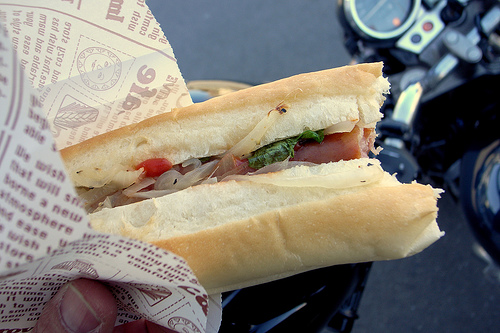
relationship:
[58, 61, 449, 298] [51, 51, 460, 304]
bread with bread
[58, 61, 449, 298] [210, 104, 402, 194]
bread with meat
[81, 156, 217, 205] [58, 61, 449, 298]
onion inside of bread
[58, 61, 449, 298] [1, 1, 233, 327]
bread inside of paper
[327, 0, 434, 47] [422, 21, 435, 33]
meter has button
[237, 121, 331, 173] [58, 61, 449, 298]
lettuce inside of a bread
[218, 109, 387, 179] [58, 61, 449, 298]
ham inside of a bread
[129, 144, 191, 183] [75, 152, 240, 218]
tomato on top of an onion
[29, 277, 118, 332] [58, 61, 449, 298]
man holding bread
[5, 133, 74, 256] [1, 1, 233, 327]
writing on a paper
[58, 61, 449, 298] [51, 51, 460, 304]
bread on bread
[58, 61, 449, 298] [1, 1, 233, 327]
bread wrapped in paper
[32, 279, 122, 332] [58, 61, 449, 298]
hand holding bread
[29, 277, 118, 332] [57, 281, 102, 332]
man has thumbnail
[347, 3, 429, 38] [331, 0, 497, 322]
gauge on top of a motorcycle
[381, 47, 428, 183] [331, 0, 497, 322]
handlebar on top of a motorcycle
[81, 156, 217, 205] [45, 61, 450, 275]
onion on inside of a sub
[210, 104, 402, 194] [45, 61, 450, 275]
meat on inside of a sub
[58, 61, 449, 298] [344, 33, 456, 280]
bread has bite taken out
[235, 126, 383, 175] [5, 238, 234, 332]
ham inside of a hand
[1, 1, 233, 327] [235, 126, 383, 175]
paper of a ham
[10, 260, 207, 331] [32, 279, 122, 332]
man has a hand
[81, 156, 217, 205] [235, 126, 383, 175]
onion on inside of a ham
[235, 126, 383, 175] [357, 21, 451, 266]
ham has eaten area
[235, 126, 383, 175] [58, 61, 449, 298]
ham inside of a bread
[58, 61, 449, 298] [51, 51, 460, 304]
bread made of bread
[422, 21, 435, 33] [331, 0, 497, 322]
button on top of a motorcycle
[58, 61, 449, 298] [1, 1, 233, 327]
bread inside of a paper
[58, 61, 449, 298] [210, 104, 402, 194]
bread has meat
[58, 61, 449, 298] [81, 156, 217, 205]
bread has onion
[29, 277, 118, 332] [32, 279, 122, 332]
man has hand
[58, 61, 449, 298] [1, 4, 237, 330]
bread has wrapping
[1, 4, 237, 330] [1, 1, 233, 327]
wrapping made of paper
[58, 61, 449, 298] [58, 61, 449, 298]
bread has bread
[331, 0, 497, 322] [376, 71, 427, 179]
motorcycle has handlebar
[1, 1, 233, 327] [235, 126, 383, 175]
paper around ham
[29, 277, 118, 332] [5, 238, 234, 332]
man has hand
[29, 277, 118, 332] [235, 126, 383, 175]
man holding ham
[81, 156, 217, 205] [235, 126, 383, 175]
onion inside of a ham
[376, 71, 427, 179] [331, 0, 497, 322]
handlebar on a motorcycle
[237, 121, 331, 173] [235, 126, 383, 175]
lettuce on inside of a ham